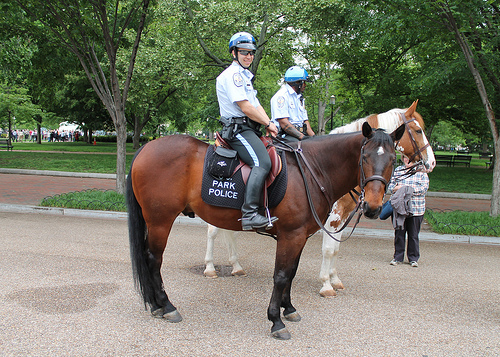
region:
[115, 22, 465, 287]
two horses standing on the street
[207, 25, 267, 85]
the policemen wearing a helmet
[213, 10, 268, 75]
the helmet is blue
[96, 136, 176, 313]
the tail is long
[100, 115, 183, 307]
the tail is black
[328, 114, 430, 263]
the horse is looking at the camera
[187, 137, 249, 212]
the saddle is black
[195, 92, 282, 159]
the police is wearing a gun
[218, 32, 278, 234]
Man wearing blue helmet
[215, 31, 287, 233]
Man wearing blue shirt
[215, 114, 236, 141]
Black handgun holstered onto belt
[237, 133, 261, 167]
Blue stripe running down black pants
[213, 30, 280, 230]
Man wearing black sunglasses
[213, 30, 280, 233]
Man wearing brown horse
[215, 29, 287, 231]
Man holding onto black harness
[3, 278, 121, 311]
Puddle behind brown horse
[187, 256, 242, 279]
Puddle underneath white and tan horse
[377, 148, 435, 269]
Person talking to police officer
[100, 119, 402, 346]
Brown horse on the sidewalk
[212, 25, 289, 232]
Man sitting on horse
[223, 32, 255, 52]
Helmet on the man's head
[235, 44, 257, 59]
Glasses on the man's face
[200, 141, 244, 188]
Pouch on side of horse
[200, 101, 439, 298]
White and brown horse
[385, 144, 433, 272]
Person wearing a plaid shirt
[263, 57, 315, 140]
Man on top of horse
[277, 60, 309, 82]
Helmet on the man's head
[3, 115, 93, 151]
Crowd of people in the background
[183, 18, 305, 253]
uniformed police man on a horse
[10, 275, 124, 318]
wet spot on the road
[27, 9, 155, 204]
large tree in the park behind the horse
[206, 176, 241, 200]
white writing on the horse saddle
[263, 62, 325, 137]
another policeman on a horse behind the first one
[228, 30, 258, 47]
blue helmet the police officer is wearing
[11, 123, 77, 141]
large group of people in the distance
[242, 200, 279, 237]
black boots the policeman is wearing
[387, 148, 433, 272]
person standing in the road near the horses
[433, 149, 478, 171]
two park benches in the park nearby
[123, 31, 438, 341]
Police officers on horses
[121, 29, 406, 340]
Police officer riding a horse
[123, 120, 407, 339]
Brown horse with a black tail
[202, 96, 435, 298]
White horse with brown spots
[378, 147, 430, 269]
Woman talking to a police officer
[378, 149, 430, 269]
Woman holding a jacket in her arms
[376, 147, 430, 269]
Woman wearing a white plaid shirt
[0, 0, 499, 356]
Police officers on horses near a large city park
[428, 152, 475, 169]
Two park benches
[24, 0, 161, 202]
A tree in a city.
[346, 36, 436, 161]
A tree in a city.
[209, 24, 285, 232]
a police officer on a horse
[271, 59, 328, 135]
a police officer on a horse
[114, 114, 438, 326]
a large brown police horse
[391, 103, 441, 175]
the head of a lightbrown horse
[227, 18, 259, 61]
a blue police helmet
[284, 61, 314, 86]
a blue police helmet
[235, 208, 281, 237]
a black boot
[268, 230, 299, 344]
the leg of a brown horse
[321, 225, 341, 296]
the leg of a brown horse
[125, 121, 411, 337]
A horse standing in the park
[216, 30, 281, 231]
A man sitting on a horse